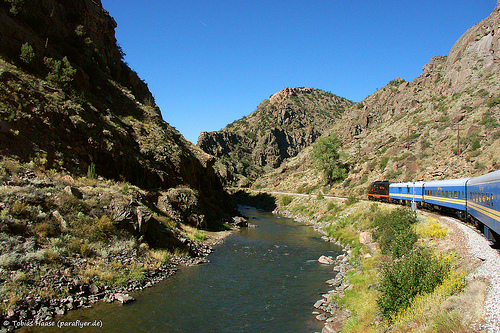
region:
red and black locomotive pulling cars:
[362, 162, 397, 207]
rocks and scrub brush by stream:
[21, 172, 157, 287]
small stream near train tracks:
[235, 190, 320, 325]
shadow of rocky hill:
[180, 125, 286, 240]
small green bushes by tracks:
[355, 193, 435, 308]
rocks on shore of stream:
[323, 224, 373, 325]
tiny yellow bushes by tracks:
[425, 217, 476, 297]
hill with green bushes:
[393, 82, 498, 152]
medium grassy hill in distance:
[213, 100, 375, 150]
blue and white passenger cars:
[386, 176, 474, 221]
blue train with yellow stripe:
[356, 167, 479, 215]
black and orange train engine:
[358, 172, 396, 211]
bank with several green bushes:
[292, 185, 471, 332]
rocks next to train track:
[457, 218, 487, 283]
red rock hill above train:
[362, 55, 499, 171]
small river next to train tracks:
[230, 192, 397, 325]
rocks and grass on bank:
[67, 214, 163, 303]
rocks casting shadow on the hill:
[28, 38, 201, 200]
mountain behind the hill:
[201, 72, 363, 189]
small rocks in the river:
[311, 245, 340, 273]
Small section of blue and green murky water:
[186, 297, 212, 309]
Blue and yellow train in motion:
[465, 181, 497, 218]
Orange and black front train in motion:
[369, 179, 389, 200]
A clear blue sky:
[314, 21, 340, 44]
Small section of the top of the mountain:
[279, 82, 304, 94]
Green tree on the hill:
[318, 140, 347, 187]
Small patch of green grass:
[353, 293, 359, 301]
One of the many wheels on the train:
[475, 220, 482, 230]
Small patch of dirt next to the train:
[441, 243, 448, 246]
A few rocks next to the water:
[159, 270, 166, 276]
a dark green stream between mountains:
[161, 188, 342, 330]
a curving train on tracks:
[361, 168, 499, 239]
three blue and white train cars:
[391, 179, 499, 217]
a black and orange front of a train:
[361, 181, 394, 203]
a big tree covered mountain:
[223, 72, 355, 171]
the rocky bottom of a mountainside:
[11, 130, 179, 262]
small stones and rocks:
[321, 256, 348, 316]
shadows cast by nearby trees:
[212, 165, 280, 215]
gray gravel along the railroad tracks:
[445, 217, 499, 304]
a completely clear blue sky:
[152, 42, 253, 94]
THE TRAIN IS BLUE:
[358, 163, 498, 253]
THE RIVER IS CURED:
[10, 153, 376, 328]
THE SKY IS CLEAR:
[100, 37, 467, 147]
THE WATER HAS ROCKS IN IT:
[0, 215, 240, 330]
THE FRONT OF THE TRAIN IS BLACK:
[355, 166, 410, 226]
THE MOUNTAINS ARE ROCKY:
[0, 0, 496, 170]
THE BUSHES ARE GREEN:
[300, 190, 498, 327]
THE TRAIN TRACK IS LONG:
[225, 172, 375, 218]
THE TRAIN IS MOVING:
[345, 167, 496, 252]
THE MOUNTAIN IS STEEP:
[5, 72, 201, 277]